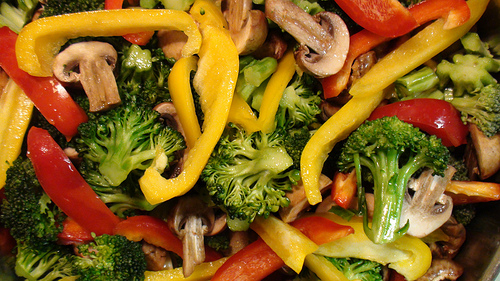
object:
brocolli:
[355, 117, 446, 243]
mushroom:
[266, 0, 356, 74]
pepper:
[379, 95, 473, 148]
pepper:
[28, 10, 216, 62]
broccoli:
[212, 131, 301, 220]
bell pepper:
[139, 17, 237, 206]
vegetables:
[84, 59, 499, 263]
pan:
[450, 230, 488, 277]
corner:
[431, 179, 492, 274]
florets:
[221, 189, 289, 218]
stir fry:
[171, 49, 367, 127]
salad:
[18, 36, 453, 263]